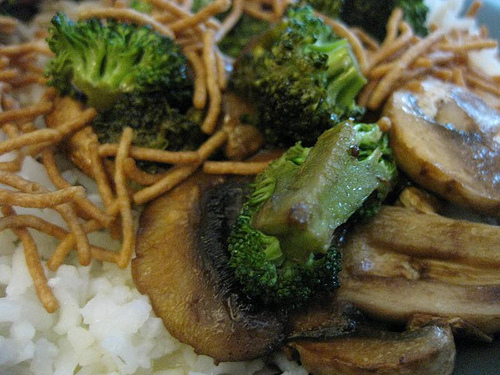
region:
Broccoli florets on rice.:
[58, 12, 390, 307]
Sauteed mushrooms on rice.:
[300, 50, 495, 371]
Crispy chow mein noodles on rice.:
[2, 10, 172, 295]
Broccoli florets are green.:
[35, 0, 390, 315]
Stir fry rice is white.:
[0, 155, 255, 370]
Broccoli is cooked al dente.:
[45, 2, 395, 332]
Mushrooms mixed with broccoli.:
[26, 2, 491, 362]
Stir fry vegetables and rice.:
[5, 5, 491, 371]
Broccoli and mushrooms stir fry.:
[42, 10, 496, 334]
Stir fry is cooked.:
[11, 5, 498, 342]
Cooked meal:
[10, 11, 494, 368]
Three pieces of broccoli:
[41, 8, 428, 325]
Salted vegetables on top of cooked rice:
[8, 2, 498, 369]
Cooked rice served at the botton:
[7, 11, 497, 366]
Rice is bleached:
[7, 5, 488, 373]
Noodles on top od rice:
[7, 2, 479, 246]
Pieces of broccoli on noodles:
[28, 2, 420, 132]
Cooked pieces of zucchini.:
[138, 81, 498, 373]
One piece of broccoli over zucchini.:
[164, 117, 401, 324]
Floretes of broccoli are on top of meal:
[40, 1, 455, 305]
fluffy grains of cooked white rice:
[10, 283, 179, 360]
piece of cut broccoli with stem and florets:
[191, 110, 396, 315]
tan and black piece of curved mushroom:
[120, 175, 280, 363]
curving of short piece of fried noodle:
[95, 110, 150, 270]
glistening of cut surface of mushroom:
[380, 55, 493, 205]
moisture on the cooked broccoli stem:
[275, 130, 390, 250]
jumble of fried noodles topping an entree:
[22, 95, 167, 261]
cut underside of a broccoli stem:
[61, 60, 117, 115]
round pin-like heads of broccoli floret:
[216, 221, 271, 286]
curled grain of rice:
[46, 273, 81, 338]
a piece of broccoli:
[219, 99, 396, 298]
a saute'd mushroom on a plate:
[129, 172, 294, 359]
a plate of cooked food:
[62, 7, 450, 344]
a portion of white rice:
[16, 238, 121, 374]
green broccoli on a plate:
[32, 8, 209, 148]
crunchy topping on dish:
[5, 97, 135, 281]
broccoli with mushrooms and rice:
[244, 13, 499, 193]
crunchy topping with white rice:
[2, 168, 182, 373]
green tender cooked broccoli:
[234, 8, 393, 305]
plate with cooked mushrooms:
[376, 65, 499, 362]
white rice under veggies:
[3, 116, 304, 371]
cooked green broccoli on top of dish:
[201, 114, 401, 300]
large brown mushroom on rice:
[128, 157, 499, 364]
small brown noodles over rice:
[0, 1, 496, 308]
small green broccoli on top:
[41, 8, 191, 145]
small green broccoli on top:
[229, 7, 366, 118]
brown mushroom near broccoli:
[376, 67, 498, 208]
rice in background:
[419, 2, 499, 82]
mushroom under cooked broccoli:
[130, 150, 499, 358]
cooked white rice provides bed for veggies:
[1, 34, 346, 370]